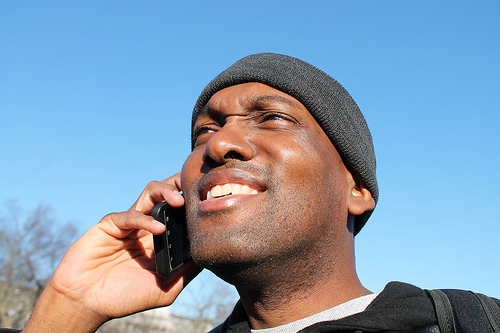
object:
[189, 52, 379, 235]
bonnet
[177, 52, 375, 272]
head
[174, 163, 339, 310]
small hairs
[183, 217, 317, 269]
jaw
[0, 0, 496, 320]
sky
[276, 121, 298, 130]
wrinkle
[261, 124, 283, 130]
wrinkle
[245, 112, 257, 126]
wrinkle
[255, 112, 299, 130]
eye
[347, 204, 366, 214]
tip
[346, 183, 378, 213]
ear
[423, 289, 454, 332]
strap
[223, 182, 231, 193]
tooth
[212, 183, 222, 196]
tooth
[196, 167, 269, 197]
lips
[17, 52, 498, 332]
man